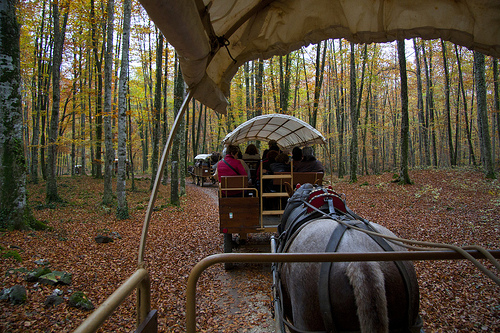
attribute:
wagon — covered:
[202, 106, 335, 278]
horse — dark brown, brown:
[272, 188, 438, 331]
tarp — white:
[208, 94, 335, 146]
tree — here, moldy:
[89, 23, 145, 232]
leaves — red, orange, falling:
[60, 21, 143, 286]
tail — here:
[340, 262, 394, 331]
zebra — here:
[273, 233, 412, 333]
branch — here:
[68, 39, 114, 223]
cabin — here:
[98, 149, 148, 191]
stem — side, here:
[378, 65, 397, 92]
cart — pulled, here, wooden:
[207, 101, 348, 282]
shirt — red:
[213, 152, 249, 195]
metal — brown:
[193, 238, 258, 327]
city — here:
[309, 59, 500, 310]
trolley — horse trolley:
[189, 145, 227, 202]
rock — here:
[33, 267, 78, 300]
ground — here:
[382, 178, 475, 268]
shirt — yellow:
[246, 150, 263, 170]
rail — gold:
[74, 272, 169, 319]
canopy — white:
[211, 115, 358, 161]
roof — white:
[220, 105, 335, 145]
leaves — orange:
[5, 169, 496, 330]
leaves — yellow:
[17, 0, 497, 167]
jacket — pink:
[212, 158, 247, 179]